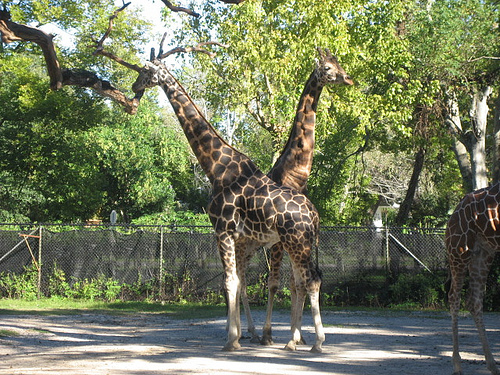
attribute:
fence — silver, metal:
[70, 223, 190, 310]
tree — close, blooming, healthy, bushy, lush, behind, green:
[347, 10, 491, 107]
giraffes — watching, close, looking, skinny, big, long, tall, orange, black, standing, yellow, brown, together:
[127, 46, 375, 285]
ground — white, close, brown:
[45, 315, 193, 372]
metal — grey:
[108, 228, 185, 286]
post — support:
[29, 212, 493, 363]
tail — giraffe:
[301, 219, 321, 271]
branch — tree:
[49, 66, 136, 98]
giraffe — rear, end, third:
[443, 168, 498, 373]